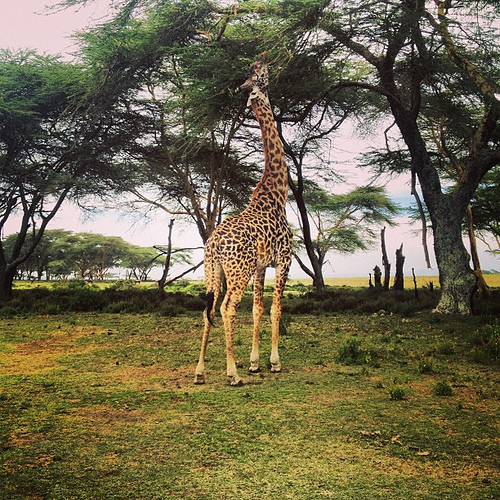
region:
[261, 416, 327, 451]
the grass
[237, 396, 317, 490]
the grass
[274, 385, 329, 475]
the grass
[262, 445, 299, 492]
the grass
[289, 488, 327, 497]
the grass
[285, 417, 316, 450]
the grass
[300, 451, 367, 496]
the grass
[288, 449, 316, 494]
the grass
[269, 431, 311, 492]
the grass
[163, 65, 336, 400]
The giraffe is yellow and brown.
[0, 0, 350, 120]
The tree is green.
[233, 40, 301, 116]
The giraffe is eating.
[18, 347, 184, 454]
Yellowish brown spots on the ground.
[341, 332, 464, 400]
Small patches of weeds.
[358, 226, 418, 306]
Broken tree limbs in the background.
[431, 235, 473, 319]
Moss growing on the tree.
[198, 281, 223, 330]
The tail is black.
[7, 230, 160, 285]
Group of trees in the distance.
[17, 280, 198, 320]
A line of bushes.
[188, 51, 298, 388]
giraffe standing on grass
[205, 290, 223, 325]
blck hair on giraffe tail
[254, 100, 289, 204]
long giraffe neck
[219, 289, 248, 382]
giraffe has four legs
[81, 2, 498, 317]
giraffe under a tree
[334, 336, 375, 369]
small green shrubs beneath tree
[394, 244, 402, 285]
dry tree trunks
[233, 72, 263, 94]
horns on giraffe head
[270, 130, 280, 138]
many brown spots on giraffe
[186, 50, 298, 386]
giraffe is eating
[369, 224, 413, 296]
stumps on the ground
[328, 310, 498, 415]
weeds in the grass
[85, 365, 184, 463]
patches of dirt on the ground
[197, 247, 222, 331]
the tail of the giraffe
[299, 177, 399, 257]
the tree canopy hangs out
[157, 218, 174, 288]
a tall dead stump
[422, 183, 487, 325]
the trunk of the tree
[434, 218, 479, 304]
fungus growing on the tree trunk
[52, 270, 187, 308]
tall shrubs in the field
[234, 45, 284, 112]
the giraffe reaches for the leaves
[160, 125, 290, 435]
a giraffe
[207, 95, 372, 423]
a giraffe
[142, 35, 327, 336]
a giraffe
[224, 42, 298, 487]
a giraffe